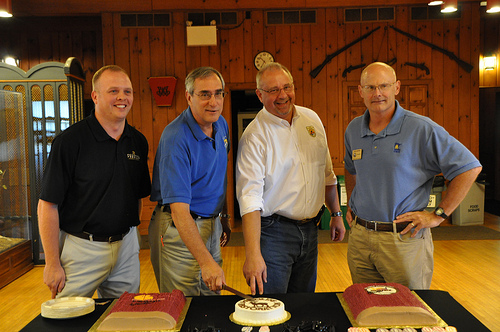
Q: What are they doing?
A: Posing.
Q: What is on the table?
A: Cake.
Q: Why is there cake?
A: Celebration.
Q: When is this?
A: Daytime.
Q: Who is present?
A: No one.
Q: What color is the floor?
A: Brown.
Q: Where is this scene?
A: Party.